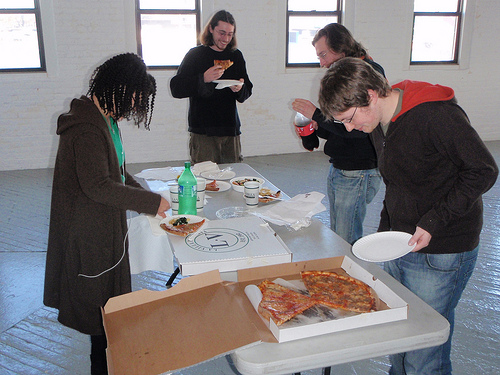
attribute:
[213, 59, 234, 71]
pizza slice — folded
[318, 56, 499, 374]
man — young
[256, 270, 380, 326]
pizza — not whole, cheese, large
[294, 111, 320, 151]
cola bottle — plastic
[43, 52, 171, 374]
woman — standing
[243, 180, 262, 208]
cup — paper, white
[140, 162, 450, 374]
table — gray, white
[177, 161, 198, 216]
bottle — green, plastic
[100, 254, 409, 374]
box — cardboard, white, open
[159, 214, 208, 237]
plate — paper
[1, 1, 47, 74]
window — closed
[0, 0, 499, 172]
wall — brick, white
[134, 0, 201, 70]
window — closed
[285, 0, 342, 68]
window — closed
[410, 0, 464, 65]
window — closed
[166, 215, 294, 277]
box — closed, cardboard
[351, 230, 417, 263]
plate — empty, white, paper, round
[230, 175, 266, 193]
bowl — white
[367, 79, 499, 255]
hoodie — black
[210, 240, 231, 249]
letter l — black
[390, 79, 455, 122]
lining — red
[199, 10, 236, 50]
hair — long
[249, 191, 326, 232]
napkins — paper, stacked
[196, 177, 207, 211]
cup — white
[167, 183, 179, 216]
cup — white